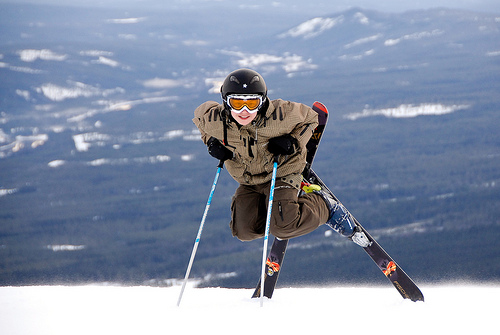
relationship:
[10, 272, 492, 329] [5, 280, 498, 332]
snow on ground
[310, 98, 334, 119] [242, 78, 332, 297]
tip of ski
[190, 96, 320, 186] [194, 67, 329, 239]
brown jacket on woman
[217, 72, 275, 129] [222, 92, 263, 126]
helmet covering head